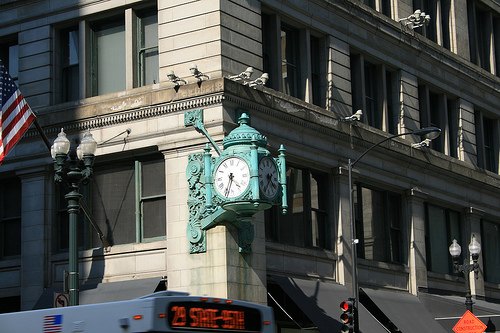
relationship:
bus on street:
[20, 297, 274, 326] [370, 311, 442, 321]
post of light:
[60, 196, 101, 310] [44, 128, 117, 182]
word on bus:
[169, 300, 261, 323] [20, 297, 274, 326]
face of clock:
[218, 170, 251, 201] [204, 129, 290, 233]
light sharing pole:
[335, 292, 360, 328] [329, 253, 373, 329]